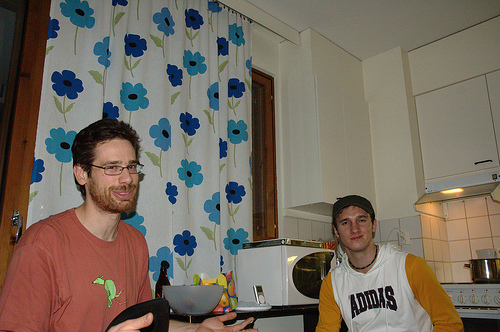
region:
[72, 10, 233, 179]
a blue floral print curtain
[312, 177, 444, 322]
a man wearing an adidas shirt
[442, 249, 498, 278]
a steel pot on the stove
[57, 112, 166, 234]
a man wearing glasses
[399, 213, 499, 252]
white tile backsplash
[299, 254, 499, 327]
a white shirt with yellow sleeves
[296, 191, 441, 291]
a man wearing a hat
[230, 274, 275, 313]
an ipod on a docking station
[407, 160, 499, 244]
a light on above the stove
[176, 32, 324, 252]
a mostly covered window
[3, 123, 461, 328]
two men standing in a kitchen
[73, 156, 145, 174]
a man wearing black glasses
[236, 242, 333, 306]
a white microwave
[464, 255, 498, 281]
a stainless steel pot on a burner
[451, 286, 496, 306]
a bunch of white dials on a stove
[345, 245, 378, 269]
man wearing a black necklace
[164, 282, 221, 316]
a frosted white bowl on a counter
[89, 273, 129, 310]
green logo of a dog on a red shirt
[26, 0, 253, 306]
white drapes with flower patterns on the window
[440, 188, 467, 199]
a white light over the stove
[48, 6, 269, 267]
window curtain is white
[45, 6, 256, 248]
curtain has blue flowers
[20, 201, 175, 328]
man's shirt is red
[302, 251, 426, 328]
man's shirt is white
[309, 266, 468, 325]
gold shirt is underneath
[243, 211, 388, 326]
microwave behind the man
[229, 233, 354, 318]
the microwave is white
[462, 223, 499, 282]
silver pot on stove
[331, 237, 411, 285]
man wearing black necklace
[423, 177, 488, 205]
light under cabinet is on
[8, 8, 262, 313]
white, blue and green curtain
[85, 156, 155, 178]
a man wearing glasses on his face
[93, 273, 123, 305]
a green dog on a shirt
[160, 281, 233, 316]
a bowl on the counter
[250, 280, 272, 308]
a music player on the counter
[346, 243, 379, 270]
man's black necklace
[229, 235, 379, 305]
a microwave on the counter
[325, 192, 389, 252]
a young man wearing a hat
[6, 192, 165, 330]
a red tee shirt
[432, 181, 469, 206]
a yellow light under the cabinet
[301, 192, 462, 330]
boy wearing a yellow and white long sleeve shirt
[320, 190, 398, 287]
man has black hair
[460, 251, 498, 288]
a pot on a stove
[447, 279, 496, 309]
control knobs of a stove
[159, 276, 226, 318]
a white bowl on a kitchen counter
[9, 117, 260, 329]
man wears a pink shirt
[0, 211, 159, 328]
a green decoration on a pink shirt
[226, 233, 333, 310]
a microwave behind a man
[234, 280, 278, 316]
an iPod in a charger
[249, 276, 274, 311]
iPod is color silver